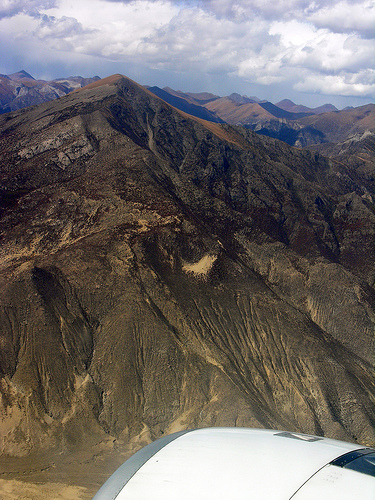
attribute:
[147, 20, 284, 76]
clouds — white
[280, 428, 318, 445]
sticker — on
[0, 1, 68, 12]
cloud — white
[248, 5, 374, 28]
cloud — white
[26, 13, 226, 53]
cloud — white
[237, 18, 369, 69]
cloud — white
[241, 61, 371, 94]
cloud — white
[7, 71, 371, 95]
sky — blue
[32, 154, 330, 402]
mountain — brown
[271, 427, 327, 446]
sticker — on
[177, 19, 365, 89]
clouds — Gray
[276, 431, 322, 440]
sticker — black, white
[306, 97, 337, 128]
ground — Forest green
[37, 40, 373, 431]
mountain — brown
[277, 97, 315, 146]
ground — Brown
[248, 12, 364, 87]
clouds — white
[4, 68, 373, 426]
mountains — large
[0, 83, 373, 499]
mountains — Brown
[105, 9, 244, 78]
sticker — on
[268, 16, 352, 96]
cloudy sky — Blue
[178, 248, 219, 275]
area — Tan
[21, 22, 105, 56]
sky — blue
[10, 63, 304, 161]
mountains — Distant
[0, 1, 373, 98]
clouds — white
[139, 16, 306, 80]
sky — blue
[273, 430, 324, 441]
sticker — on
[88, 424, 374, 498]
airplane — White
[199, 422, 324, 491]
sticker — on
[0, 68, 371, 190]
mountains — Distant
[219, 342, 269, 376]
line — on